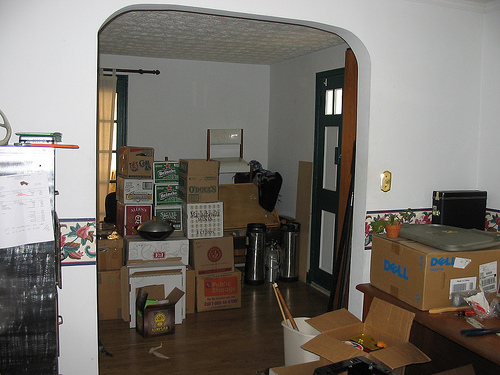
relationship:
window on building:
[96, 90, 118, 222] [97, 87, 120, 238]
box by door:
[193, 270, 245, 314] [304, 66, 346, 299]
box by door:
[185, 200, 227, 241] [304, 66, 346, 299]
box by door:
[126, 234, 190, 269] [304, 66, 346, 299]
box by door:
[114, 146, 156, 181] [304, 66, 346, 299]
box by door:
[179, 156, 219, 203] [304, 66, 346, 299]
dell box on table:
[368, 225, 498, 313] [417, 315, 485, 365]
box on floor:
[117, 147, 153, 178] [99, 332, 266, 371]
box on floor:
[179, 156, 219, 203] [99, 332, 266, 371]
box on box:
[182, 202, 224, 239] [193, 235, 234, 276]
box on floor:
[198, 270, 241, 312] [99, 332, 266, 371]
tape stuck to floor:
[147, 340, 168, 359] [107, 317, 272, 372]